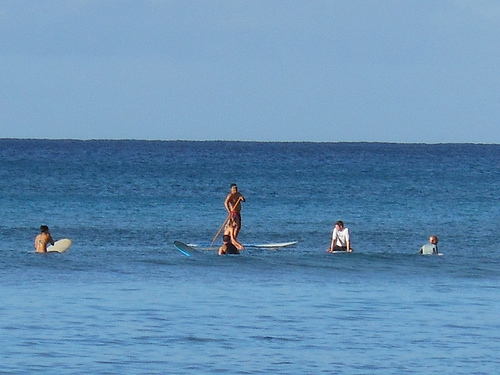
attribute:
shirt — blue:
[417, 244, 437, 258]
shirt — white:
[328, 225, 350, 245]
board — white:
[186, 240, 298, 249]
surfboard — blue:
[172, 235, 206, 260]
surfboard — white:
[167, 219, 315, 267]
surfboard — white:
[44, 233, 87, 253]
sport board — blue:
[172, 238, 202, 259]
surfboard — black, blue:
[165, 232, 215, 265]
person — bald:
[417, 235, 440, 257]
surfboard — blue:
[173, 237, 298, 258]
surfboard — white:
[3, 147, 498, 364]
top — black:
[223, 242, 240, 256]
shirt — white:
[330, 227, 351, 251]